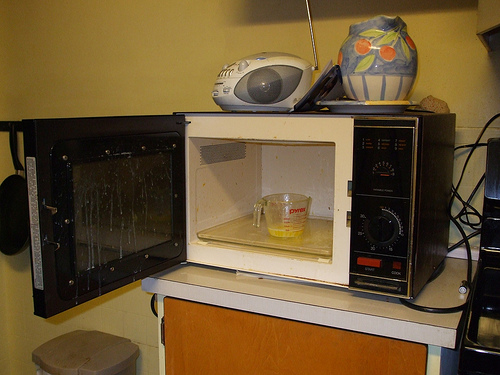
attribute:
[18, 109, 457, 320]
microwave — black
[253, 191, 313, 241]
cup — yellow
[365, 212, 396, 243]
knob — black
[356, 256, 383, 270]
button — red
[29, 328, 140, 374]
stool — below